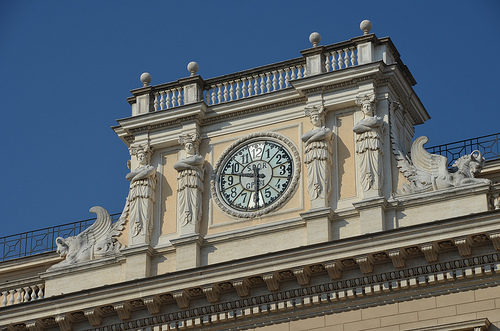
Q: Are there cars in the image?
A: No, there are no cars.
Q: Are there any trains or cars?
A: No, there are no cars or trains.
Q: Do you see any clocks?
A: Yes, there is a clock.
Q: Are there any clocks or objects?
A: Yes, there is a clock.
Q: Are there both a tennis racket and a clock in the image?
A: No, there is a clock but no rackets.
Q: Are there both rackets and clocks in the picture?
A: No, there is a clock but no rackets.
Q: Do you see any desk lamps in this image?
A: No, there are no desk lamps.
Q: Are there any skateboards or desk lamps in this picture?
A: No, there are no desk lamps or skateboards.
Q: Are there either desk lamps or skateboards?
A: No, there are no desk lamps or skateboards.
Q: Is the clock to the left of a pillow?
A: No, the clock is to the left of a statue.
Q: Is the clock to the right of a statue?
A: No, the clock is to the left of a statue.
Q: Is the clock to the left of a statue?
A: Yes, the clock is to the left of a statue.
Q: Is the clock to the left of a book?
A: No, the clock is to the left of a statue.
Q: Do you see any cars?
A: No, there are no cars.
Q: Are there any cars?
A: No, there are no cars.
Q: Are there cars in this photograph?
A: No, there are no cars.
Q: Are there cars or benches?
A: No, there are no cars or benches.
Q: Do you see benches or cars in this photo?
A: No, there are no cars or benches.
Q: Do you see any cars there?
A: No, there are no cars.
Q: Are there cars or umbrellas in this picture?
A: No, there are no cars or umbrellas.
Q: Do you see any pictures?
A: No, there are no pictures.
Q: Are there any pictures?
A: No, there are no pictures.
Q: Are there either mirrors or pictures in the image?
A: No, there are no pictures or mirrors.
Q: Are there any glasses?
A: No, there are no glasses.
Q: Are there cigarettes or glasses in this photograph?
A: No, there are no glasses or cigarettes.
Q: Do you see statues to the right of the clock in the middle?
A: Yes, there is a statue to the right of the clock.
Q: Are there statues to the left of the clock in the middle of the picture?
A: No, the statue is to the right of the clock.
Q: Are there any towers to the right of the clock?
A: No, there is a statue to the right of the clock.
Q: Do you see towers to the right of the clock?
A: No, there is a statue to the right of the clock.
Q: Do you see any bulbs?
A: No, there are no bulbs.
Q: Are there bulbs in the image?
A: No, there are no bulbs.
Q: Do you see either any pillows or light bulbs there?
A: No, there are no light bulbs or pillows.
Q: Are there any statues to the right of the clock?
A: Yes, there is a statue to the right of the clock.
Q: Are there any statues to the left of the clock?
A: No, the statue is to the right of the clock.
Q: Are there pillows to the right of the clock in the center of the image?
A: No, there is a statue to the right of the clock.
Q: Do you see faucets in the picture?
A: No, there are no faucets.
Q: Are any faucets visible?
A: No, there are no faucets.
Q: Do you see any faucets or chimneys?
A: No, there are no faucets or chimneys.